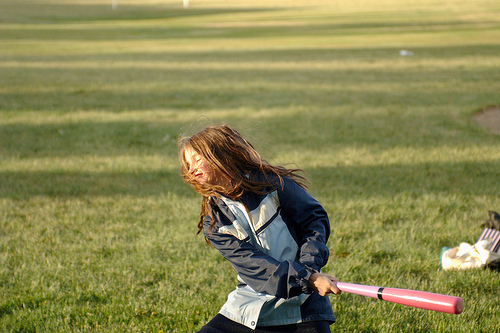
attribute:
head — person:
[162, 118, 271, 214]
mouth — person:
[192, 167, 203, 185]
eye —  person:
[192, 156, 203, 166]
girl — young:
[174, 125, 462, 327]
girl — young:
[175, 119, 342, 324]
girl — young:
[166, 122, 337, 329]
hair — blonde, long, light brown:
[180, 122, 303, 232]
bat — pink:
[326, 280, 460, 314]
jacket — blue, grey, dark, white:
[194, 166, 340, 326]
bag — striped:
[470, 223, 484, 255]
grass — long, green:
[26, 214, 200, 312]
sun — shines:
[26, 198, 55, 221]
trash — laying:
[392, 40, 418, 64]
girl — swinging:
[163, 95, 345, 331]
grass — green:
[13, 279, 108, 331]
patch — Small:
[18, 262, 86, 327]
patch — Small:
[91, 280, 158, 330]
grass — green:
[16, 233, 172, 324]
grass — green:
[83, 266, 179, 331]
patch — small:
[130, 280, 176, 318]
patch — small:
[71, 167, 115, 220]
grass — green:
[30, 120, 147, 291]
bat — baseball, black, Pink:
[334, 274, 465, 325]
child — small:
[178, 116, 338, 331]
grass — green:
[20, 32, 103, 129]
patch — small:
[16, 23, 56, 65]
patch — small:
[103, 41, 163, 81]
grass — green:
[48, 26, 153, 105]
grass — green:
[72, 30, 337, 106]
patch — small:
[156, 22, 242, 70]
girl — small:
[200, 132, 320, 323]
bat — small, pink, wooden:
[307, 257, 465, 321]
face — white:
[172, 138, 210, 188]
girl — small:
[242, 246, 296, 295]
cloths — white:
[458, 245, 472, 272]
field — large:
[64, 128, 354, 259]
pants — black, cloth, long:
[202, 254, 327, 333]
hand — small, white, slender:
[308, 269, 344, 303]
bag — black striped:
[475, 229, 498, 244]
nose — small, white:
[185, 164, 198, 177]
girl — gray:
[179, 109, 335, 333]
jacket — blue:
[216, 224, 318, 291]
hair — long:
[205, 139, 287, 195]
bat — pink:
[299, 285, 468, 333]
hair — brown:
[220, 136, 300, 181]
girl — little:
[168, 141, 334, 333]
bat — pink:
[308, 277, 468, 320]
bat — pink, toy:
[325, 275, 456, 315]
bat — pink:
[329, 274, 462, 316]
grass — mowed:
[9, 71, 157, 313]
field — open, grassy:
[77, 136, 197, 306]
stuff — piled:
[434, 209, 498, 278]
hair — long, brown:
[175, 124, 303, 221]